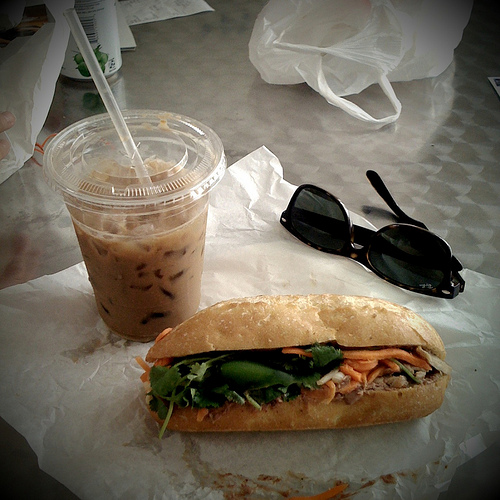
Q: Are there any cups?
A: Yes, there is a cup.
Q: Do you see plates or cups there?
A: Yes, there is a cup.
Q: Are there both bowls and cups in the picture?
A: No, there is a cup but no bowls.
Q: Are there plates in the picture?
A: No, there are no plates.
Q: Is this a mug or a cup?
A: This is a cup.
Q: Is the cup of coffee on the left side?
A: Yes, the cup is on the left of the image.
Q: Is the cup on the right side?
A: No, the cup is on the left of the image.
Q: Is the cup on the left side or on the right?
A: The cup is on the left of the image.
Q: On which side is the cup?
A: The cup is on the left of the image.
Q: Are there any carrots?
A: Yes, there are carrots.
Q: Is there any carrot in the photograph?
A: Yes, there are carrots.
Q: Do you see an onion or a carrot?
A: Yes, there are carrots.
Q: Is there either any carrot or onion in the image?
A: Yes, there are carrots.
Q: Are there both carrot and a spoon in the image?
A: No, there are carrots but no spoons.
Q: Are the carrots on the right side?
A: Yes, the carrots are on the right of the image.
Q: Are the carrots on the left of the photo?
A: No, the carrots are on the right of the image.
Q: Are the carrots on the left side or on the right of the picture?
A: The carrots are on the right of the image.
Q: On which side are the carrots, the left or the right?
A: The carrots are on the right of the image.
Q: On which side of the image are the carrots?
A: The carrots are on the right of the image.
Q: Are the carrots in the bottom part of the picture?
A: Yes, the carrots are in the bottom of the image.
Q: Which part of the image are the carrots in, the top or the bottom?
A: The carrots are in the bottom of the image.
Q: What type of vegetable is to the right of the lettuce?
A: The vegetables are carrots.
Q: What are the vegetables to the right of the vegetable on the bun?
A: The vegetables are carrots.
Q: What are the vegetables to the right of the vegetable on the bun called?
A: The vegetables are carrots.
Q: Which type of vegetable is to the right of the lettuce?
A: The vegetables are carrots.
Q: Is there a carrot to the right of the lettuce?
A: Yes, there are carrots to the right of the lettuce.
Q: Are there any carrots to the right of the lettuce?
A: Yes, there are carrots to the right of the lettuce.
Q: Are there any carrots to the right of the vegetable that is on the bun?
A: Yes, there are carrots to the right of the lettuce.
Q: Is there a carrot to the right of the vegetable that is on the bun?
A: Yes, there are carrots to the right of the lettuce.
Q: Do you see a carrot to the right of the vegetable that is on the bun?
A: Yes, there are carrots to the right of the lettuce.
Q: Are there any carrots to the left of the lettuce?
A: No, the carrots are to the right of the lettuce.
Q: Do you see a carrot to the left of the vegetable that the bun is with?
A: No, the carrots are to the right of the lettuce.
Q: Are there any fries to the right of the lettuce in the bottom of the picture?
A: No, there are carrots to the right of the lettuce.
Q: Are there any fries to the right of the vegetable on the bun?
A: No, there are carrots to the right of the lettuce.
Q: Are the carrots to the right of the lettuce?
A: Yes, the carrots are to the right of the lettuce.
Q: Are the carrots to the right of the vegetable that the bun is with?
A: Yes, the carrots are to the right of the lettuce.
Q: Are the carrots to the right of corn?
A: No, the carrots are to the right of the lettuce.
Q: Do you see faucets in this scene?
A: No, there are no faucets.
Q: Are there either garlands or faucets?
A: No, there are no faucets or garlands.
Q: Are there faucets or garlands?
A: No, there are no faucets or garlands.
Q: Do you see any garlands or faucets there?
A: No, there are no faucets or garlands.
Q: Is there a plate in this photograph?
A: No, there are no plates.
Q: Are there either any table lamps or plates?
A: No, there are no plates or table lamps.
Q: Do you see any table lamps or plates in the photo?
A: No, there are no plates or table lamps.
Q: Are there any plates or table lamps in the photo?
A: No, there are no plates or table lamps.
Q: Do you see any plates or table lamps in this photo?
A: No, there are no plates or table lamps.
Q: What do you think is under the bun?
A: The paper is under the bun.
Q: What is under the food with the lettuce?
A: The paper is under the bun.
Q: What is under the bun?
A: The paper is under the bun.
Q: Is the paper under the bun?
A: Yes, the paper is under the bun.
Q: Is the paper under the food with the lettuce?
A: Yes, the paper is under the bun.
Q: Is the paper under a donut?
A: No, the paper is under the bun.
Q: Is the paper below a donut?
A: No, the paper is below the bun.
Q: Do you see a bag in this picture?
A: Yes, there is a bag.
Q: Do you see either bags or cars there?
A: Yes, there is a bag.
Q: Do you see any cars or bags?
A: Yes, there is a bag.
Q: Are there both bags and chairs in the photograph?
A: No, there is a bag but no chairs.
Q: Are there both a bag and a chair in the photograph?
A: No, there is a bag but no chairs.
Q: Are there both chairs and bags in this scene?
A: No, there is a bag but no chairs.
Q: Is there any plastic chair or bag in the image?
A: Yes, there is a plastic bag.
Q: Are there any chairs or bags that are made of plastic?
A: Yes, the bag is made of plastic.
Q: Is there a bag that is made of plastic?
A: Yes, there is a bag that is made of plastic.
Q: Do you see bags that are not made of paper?
A: Yes, there is a bag that is made of plastic.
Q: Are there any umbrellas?
A: No, there are no umbrellas.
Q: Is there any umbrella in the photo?
A: No, there are no umbrellas.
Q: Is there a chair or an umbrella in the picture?
A: No, there are no umbrellas or chairs.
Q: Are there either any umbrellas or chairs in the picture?
A: No, there are no umbrellas or chairs.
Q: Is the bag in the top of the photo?
A: Yes, the bag is in the top of the image.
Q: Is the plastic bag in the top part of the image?
A: Yes, the bag is in the top of the image.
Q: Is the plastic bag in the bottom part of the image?
A: No, the bag is in the top of the image.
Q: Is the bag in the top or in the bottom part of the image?
A: The bag is in the top of the image.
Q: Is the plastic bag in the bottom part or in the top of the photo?
A: The bag is in the top of the image.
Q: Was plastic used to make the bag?
A: Yes, the bag is made of plastic.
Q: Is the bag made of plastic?
A: Yes, the bag is made of plastic.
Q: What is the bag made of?
A: The bag is made of plastic.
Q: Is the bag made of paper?
A: No, the bag is made of plastic.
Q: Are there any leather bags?
A: No, there is a bag but it is made of plastic.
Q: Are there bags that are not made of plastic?
A: No, there is a bag but it is made of plastic.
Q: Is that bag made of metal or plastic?
A: The bag is made of plastic.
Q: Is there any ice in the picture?
A: Yes, there is ice.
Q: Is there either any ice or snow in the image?
A: Yes, there is ice.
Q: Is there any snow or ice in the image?
A: Yes, there is ice.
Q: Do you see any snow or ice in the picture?
A: Yes, there is ice.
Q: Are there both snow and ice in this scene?
A: No, there is ice but no snow.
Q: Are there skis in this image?
A: No, there are no skis.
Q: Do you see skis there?
A: No, there are no skis.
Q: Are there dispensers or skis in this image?
A: No, there are no skis or dispensers.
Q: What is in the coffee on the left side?
A: The ice is in the coffee.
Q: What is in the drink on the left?
A: The ice is in the coffee.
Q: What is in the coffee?
A: The ice is in the coffee.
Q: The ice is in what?
A: The ice is in the coffee.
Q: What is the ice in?
A: The ice is in the coffee.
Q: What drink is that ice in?
A: The ice is in the coffee.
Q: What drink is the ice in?
A: The ice is in the coffee.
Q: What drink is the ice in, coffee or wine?
A: The ice is in coffee.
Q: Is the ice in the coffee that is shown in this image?
A: Yes, the ice is in the coffee.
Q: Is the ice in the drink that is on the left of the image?
A: Yes, the ice is in the coffee.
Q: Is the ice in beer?
A: No, the ice is in the coffee.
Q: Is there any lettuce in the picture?
A: Yes, there is lettuce.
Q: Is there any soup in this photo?
A: No, there is no soup.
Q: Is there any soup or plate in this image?
A: No, there are no soup or plates.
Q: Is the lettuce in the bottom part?
A: Yes, the lettuce is in the bottom of the image.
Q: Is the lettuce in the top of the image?
A: No, the lettuce is in the bottom of the image.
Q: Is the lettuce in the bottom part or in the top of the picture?
A: The lettuce is in the bottom of the image.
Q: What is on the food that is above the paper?
A: The lettuce is on the bun.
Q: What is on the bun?
A: The lettuce is on the bun.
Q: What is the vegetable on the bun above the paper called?
A: The vegetable is lettuce.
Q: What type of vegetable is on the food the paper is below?
A: The vegetable is lettuce.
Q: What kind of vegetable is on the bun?
A: The vegetable is lettuce.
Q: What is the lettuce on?
A: The lettuce is on the bun.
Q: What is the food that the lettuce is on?
A: The food is a bun.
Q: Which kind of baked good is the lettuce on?
A: The lettuce is on the bun.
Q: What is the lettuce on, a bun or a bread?
A: The lettuce is on a bun.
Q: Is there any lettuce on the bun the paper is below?
A: Yes, there is lettuce on the bun.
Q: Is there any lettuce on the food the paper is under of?
A: Yes, there is lettuce on the bun.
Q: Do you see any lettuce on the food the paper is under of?
A: Yes, there is lettuce on the bun.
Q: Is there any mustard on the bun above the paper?
A: No, there is lettuce on the bun.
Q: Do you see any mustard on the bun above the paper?
A: No, there is lettuce on the bun.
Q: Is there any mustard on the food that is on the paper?
A: No, there is lettuce on the bun.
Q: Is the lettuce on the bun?
A: Yes, the lettuce is on the bun.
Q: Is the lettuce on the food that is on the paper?
A: Yes, the lettuce is on the bun.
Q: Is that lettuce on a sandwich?
A: No, the lettuce is on the bun.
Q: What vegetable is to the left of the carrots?
A: The vegetable is lettuce.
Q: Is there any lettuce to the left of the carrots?
A: Yes, there is lettuce to the left of the carrots.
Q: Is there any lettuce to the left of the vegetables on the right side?
A: Yes, there is lettuce to the left of the carrots.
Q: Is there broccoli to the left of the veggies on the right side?
A: No, there is lettuce to the left of the carrots.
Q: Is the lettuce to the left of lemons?
A: No, the lettuce is to the left of the carrots.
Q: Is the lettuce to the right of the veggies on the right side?
A: No, the lettuce is to the left of the carrots.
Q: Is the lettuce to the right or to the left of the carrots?
A: The lettuce is to the left of the carrots.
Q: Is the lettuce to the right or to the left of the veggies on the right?
A: The lettuce is to the left of the carrots.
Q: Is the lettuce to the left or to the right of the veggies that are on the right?
A: The lettuce is to the left of the carrots.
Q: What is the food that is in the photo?
A: The food is a bun.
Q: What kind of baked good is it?
A: The food is a bun.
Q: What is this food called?
A: This is a bun.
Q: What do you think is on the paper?
A: The bun is on the paper.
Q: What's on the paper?
A: The bun is on the paper.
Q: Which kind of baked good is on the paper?
A: The food is a bun.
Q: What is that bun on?
A: The bun is on the paper.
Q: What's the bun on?
A: The bun is on the paper.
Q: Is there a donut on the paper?
A: No, there is a bun on the paper.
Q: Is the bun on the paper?
A: Yes, the bun is on the paper.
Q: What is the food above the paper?
A: The food is a bun.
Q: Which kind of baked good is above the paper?
A: The food is a bun.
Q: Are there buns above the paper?
A: Yes, there is a bun above the paper.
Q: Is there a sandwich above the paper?
A: No, there is a bun above the paper.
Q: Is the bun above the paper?
A: Yes, the bun is above the paper.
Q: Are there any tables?
A: Yes, there is a table.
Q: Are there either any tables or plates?
A: Yes, there is a table.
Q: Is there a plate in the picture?
A: No, there are no plates.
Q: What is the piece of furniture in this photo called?
A: The piece of furniture is a table.